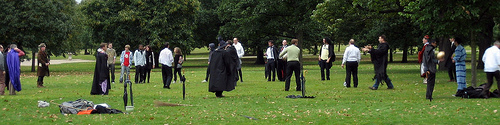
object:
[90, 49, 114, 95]
garment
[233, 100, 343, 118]
flowers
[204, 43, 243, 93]
robe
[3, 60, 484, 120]
ground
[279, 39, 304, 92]
person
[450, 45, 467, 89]
jumpsuit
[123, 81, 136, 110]
umbrella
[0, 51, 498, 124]
grass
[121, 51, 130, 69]
shirt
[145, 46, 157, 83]
girl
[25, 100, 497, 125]
leaves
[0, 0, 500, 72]
trees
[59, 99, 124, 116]
clothes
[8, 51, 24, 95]
clothes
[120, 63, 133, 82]
jean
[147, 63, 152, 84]
pant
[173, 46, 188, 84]
woman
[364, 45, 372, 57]
car